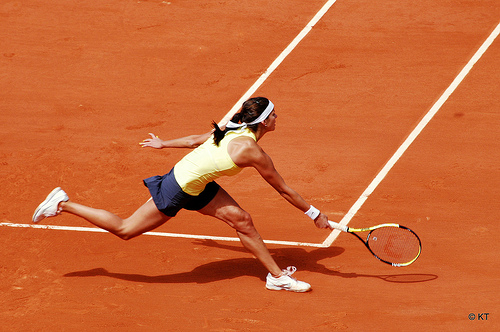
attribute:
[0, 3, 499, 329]
court — tennis, brown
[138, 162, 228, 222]
skirt —  blue 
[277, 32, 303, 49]
line — white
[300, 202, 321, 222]
sweat band — White , black 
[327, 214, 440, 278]
racket — tennis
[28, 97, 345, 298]
player — female 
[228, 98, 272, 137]
headband — white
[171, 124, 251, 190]
shirt — yellow 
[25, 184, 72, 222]
tennis shoe — white 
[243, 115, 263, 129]
band — white, black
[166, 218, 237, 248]
line — white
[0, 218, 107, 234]
line — white